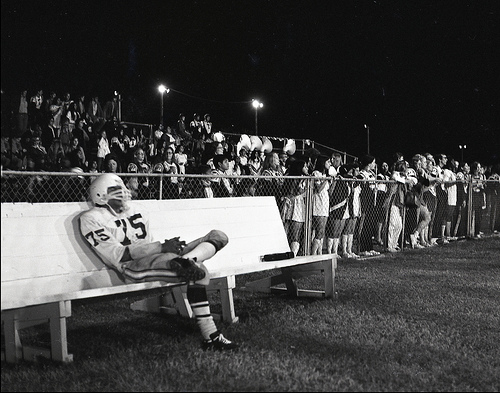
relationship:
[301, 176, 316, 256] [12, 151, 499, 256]
post supporting fence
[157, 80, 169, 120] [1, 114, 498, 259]
lights behind stands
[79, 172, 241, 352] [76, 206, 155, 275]
football player wearing jersey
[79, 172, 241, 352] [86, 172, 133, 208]
football player wearing helmet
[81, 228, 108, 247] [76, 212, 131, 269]
number on players sleeve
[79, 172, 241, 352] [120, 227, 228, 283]
football player wearing pants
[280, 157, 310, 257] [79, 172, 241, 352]
girl behind football player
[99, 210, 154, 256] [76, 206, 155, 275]
number on jersey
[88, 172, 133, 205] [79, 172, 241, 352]
helmet on football player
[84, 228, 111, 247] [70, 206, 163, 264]
number on arm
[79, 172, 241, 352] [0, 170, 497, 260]
football player lined up at fence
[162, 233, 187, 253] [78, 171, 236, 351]
hands of number 75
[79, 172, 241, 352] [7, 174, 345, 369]
football player sitting alone on bench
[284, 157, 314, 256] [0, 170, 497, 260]
girl leaning on fence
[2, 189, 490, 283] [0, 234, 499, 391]
sideline of football field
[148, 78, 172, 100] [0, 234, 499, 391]
light shining on football field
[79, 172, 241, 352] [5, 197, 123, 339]
football player relaxing on bench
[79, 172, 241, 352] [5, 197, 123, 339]
football player sitting on bench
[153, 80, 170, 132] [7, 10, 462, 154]
light poles in background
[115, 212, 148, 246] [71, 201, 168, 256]
number written on jersey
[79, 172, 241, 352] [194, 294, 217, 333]
football player wearing sock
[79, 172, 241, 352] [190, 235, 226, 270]
football player wearing sock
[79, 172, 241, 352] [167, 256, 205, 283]
football player wearing shoe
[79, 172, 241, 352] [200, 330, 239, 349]
football player wearing shoe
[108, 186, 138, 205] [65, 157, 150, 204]
faceguard on helmet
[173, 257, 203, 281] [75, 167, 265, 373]
cleat on player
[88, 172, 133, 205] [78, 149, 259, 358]
helmet on player